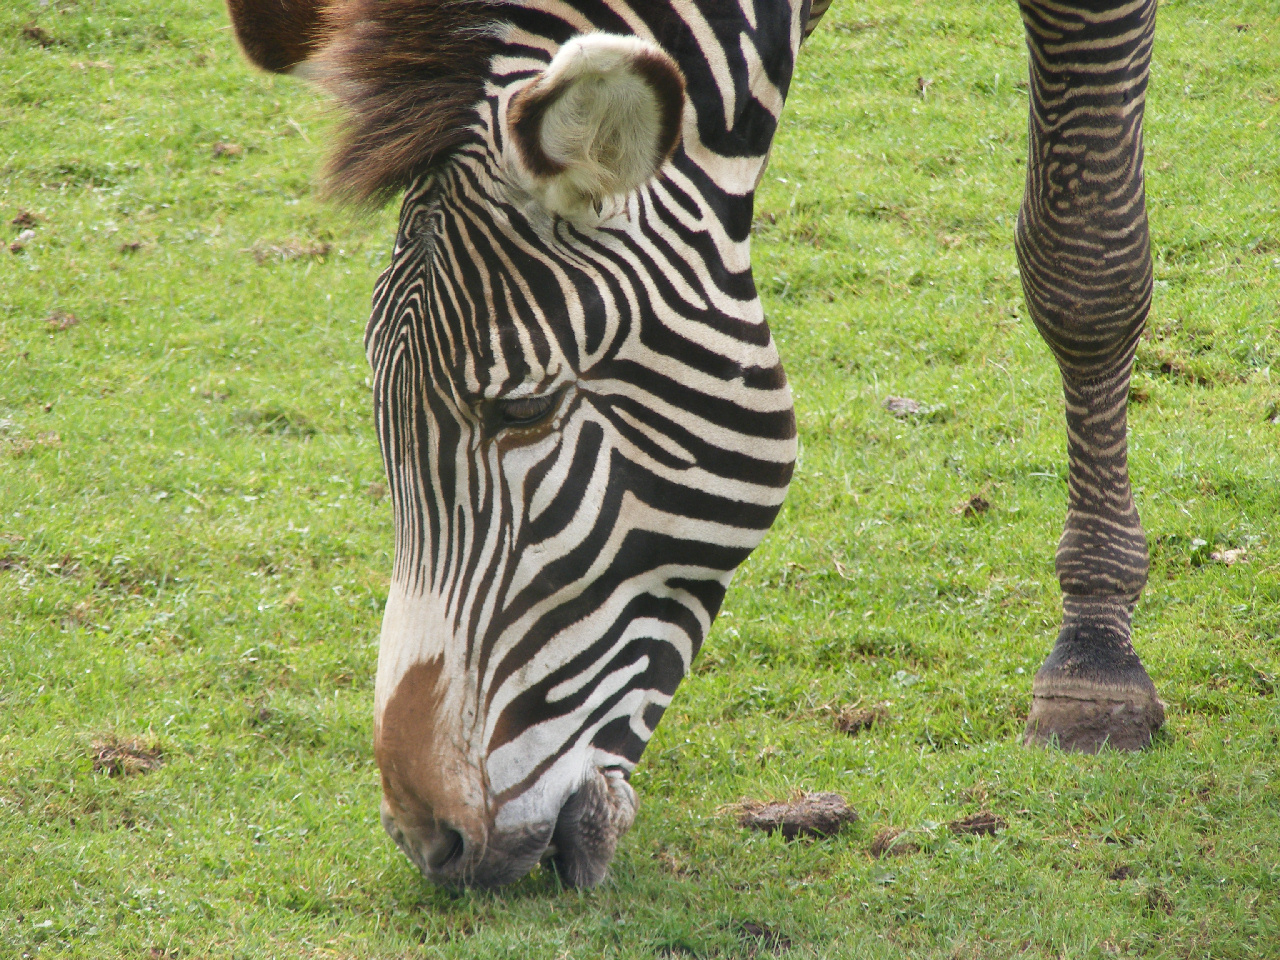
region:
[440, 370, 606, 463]
eye of the zebra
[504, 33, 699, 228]
ear of the zebra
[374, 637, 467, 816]
brown spot on the nose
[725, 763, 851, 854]
tufts of brown grass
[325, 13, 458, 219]
mane on the zebra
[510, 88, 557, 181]
brown on the ear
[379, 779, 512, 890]
Zebra has brown nose.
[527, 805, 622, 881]
Zebra has black and brown mouth.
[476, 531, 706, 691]
Zebra has black and white face.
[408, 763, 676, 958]
Zebra is eating grass.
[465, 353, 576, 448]
Zebra has dark eye.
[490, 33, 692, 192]
Zebra has white and black ear.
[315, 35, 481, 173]
Zebra has dark mane on head.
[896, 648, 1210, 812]
Zebra is standing in green grass.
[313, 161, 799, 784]
Zebra is covered in stripes.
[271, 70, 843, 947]
Zebra is bending head down towards ground.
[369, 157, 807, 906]
black and white face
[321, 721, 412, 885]
zebra has brown nose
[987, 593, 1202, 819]
zebra has grey hoof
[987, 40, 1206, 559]
brown and black leg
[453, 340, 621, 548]
zebra's eye is black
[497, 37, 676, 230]
black and white ear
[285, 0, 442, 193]
black and white mane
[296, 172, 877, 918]
black and white zebra grazing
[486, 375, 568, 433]
the black eye of the zebra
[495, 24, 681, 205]
the ear of the zebra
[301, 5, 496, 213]
the hair of the zebra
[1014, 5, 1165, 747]
the striped leg of the zebra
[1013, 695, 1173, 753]
the black hoof of the zebra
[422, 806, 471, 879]
the nostril of the zebra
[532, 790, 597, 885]
the mouth of the zebra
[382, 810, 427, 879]
the nostril of the zebra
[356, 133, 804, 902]
the head of the zebra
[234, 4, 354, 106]
the ear of the zebra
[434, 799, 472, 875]
the hole of a nostil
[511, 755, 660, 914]
a mouth eating grass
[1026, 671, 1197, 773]
the brown hoof of zebra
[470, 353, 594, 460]
the eye of a zebra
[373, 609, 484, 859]
a brown spot on a nose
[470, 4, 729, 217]
the ear on the zebra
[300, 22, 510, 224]
brown hair of mane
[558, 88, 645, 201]
white fur in the ear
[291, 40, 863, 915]
the head of a zebra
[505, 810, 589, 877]
open mouth of the zebra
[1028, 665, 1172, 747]
hoof of the zebra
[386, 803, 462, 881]
nostrils on the zebra's face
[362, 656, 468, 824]
brown spot on the zebra's nose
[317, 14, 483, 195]
black hair on the zebra's head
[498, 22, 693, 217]
white ear with black trim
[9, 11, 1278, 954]
grass the zebra is grazing on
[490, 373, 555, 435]
black eye of the zebra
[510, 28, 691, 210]
a left ear of a zebra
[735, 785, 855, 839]
a spot of overturned sod from hooves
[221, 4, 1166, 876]
a zebra eating grass in a field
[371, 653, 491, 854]
a brown streak on a zebra's nose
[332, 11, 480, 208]
short dark mane of a zebra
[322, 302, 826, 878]
A head of the zebra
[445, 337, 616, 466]
The eye of the zebra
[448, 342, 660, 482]
A eye of the zebra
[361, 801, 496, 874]
The nostrils of the zebra